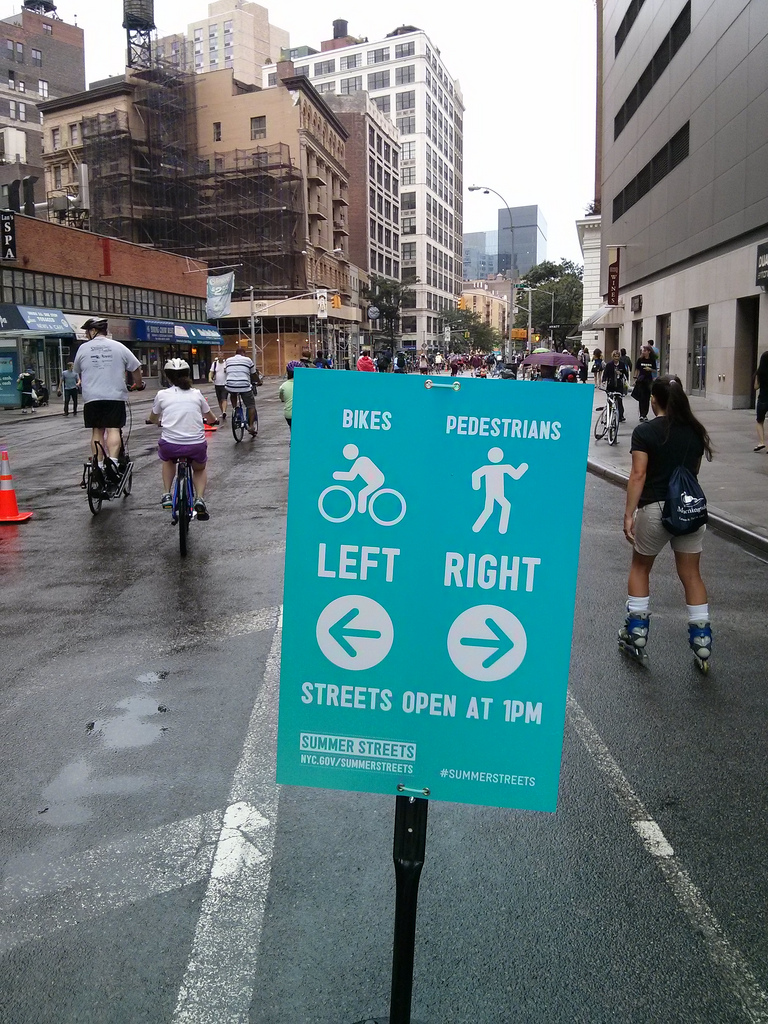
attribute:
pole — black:
[387, 790, 433, 1017]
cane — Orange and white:
[4, 447, 34, 527]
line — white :
[563, 689, 752, 1021]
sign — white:
[270, 365, 605, 845]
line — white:
[154, 587, 295, 1021]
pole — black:
[385, 791, 431, 1021]